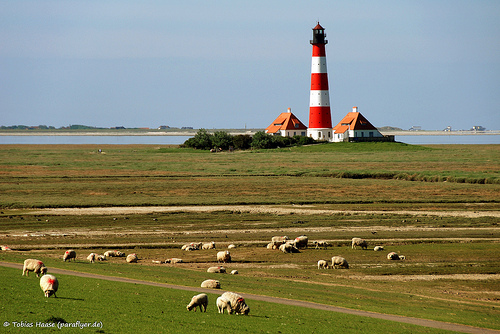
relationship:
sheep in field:
[14, 223, 414, 333] [3, 141, 497, 331]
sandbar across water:
[0, 124, 491, 134] [0, 134, 498, 144]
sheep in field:
[216, 295, 260, 322] [3, 141, 497, 331]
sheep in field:
[158, 223, 325, 324] [3, 141, 497, 331]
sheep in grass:
[293, 229, 310, 249] [4, 145, 498, 330]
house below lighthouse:
[267, 108, 305, 135] [307, 24, 332, 140]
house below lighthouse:
[334, 107, 384, 137] [307, 24, 332, 140]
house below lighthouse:
[328, 109, 384, 142] [303, 20, 336, 141]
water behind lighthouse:
[8, 129, 498, 150] [309, 14, 335, 141]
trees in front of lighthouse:
[179, 122, 309, 152] [305, 16, 335, 141]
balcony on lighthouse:
[303, 20, 333, 47] [300, 15, 335, 142]